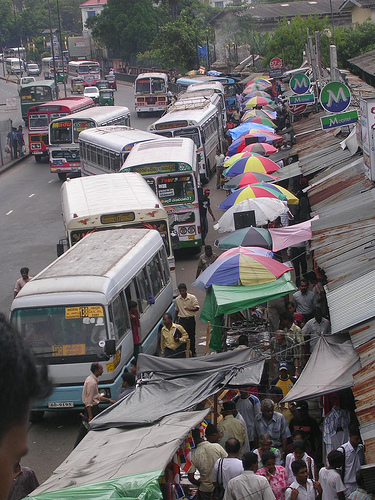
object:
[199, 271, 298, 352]
tarp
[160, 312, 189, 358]
man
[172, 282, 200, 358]
man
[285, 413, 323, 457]
shirt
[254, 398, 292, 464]
man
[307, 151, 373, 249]
roof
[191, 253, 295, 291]
umbrella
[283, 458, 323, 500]
shopper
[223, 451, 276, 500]
shopper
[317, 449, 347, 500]
shopper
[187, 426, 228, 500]
shopper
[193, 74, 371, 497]
market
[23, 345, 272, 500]
tarp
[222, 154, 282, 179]
umbrella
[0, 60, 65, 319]
ground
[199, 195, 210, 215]
shirt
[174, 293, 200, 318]
shirt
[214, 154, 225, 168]
shirt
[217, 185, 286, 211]
umbrella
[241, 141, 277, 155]
umbrella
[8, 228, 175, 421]
bus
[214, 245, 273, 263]
umbrella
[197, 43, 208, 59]
banner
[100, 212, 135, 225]
sign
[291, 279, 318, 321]
people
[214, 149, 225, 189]
people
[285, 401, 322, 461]
people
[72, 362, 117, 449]
people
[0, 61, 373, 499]
street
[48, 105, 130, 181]
bus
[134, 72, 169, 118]
bus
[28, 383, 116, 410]
bumper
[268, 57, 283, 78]
sign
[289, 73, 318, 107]
sign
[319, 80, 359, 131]
sign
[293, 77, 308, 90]
white m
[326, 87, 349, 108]
white m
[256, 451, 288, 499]
woman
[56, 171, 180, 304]
bus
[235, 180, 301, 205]
umbrella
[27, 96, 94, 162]
bus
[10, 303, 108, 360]
windshield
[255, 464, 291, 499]
pink shirt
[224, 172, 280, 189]
umbrella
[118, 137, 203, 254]
bus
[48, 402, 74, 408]
plate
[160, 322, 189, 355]
shirt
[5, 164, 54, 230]
road